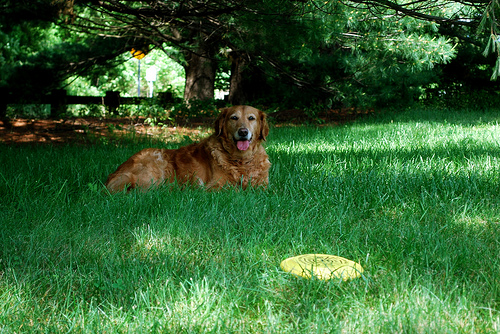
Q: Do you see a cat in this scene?
A: No, there are no cats.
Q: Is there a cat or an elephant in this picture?
A: No, there are no cats or elephants.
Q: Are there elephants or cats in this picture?
A: No, there are no cats or elephants.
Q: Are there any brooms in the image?
A: No, there are no brooms.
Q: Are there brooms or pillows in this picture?
A: No, there are no brooms or pillows.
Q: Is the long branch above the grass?
A: Yes, the branch is above the grass.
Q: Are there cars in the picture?
A: No, there are no cars.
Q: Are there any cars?
A: No, there are no cars.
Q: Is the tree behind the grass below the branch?
A: Yes, the tree is behind the grass.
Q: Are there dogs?
A: Yes, there is a dog.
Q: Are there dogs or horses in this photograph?
A: Yes, there is a dog.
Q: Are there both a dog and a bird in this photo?
A: No, there is a dog but no birds.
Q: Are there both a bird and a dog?
A: No, there is a dog but no birds.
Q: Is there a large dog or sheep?
A: Yes, there is a large dog.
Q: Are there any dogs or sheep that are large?
A: Yes, the dog is large.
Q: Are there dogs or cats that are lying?
A: Yes, the dog is lying.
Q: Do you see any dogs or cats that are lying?
A: Yes, the dog is lying.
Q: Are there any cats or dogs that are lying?
A: Yes, the dog is lying.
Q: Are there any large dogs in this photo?
A: Yes, there is a large dog.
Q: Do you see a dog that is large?
A: Yes, there is a dog that is large.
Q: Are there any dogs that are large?
A: Yes, there is a dog that is large.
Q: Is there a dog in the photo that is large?
A: Yes, there is a dog that is large.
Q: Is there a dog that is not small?
A: Yes, there is a large dog.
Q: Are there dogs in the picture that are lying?
A: Yes, there is a dog that is lying.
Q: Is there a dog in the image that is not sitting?
A: Yes, there is a dog that is lying.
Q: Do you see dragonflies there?
A: No, there are no dragonflies.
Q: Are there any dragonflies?
A: No, there are no dragonflies.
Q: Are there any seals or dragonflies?
A: No, there are no dragonflies or seals.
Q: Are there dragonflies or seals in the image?
A: No, there are no dragonflies or seals.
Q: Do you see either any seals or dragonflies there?
A: No, there are no dragonflies or seals.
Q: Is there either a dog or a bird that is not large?
A: No, there is a dog but it is large.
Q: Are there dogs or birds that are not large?
A: No, there is a dog but it is large.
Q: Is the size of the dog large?
A: Yes, the dog is large.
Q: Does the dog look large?
A: Yes, the dog is large.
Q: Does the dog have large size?
A: Yes, the dog is large.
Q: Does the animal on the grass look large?
A: Yes, the dog is large.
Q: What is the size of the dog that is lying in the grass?
A: The dog is large.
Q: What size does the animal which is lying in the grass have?
A: The dog has large size.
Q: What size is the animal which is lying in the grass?
A: The dog is large.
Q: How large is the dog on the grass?
A: The dog is large.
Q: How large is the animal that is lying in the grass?
A: The dog is large.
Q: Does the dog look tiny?
A: No, the dog is large.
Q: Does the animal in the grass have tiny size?
A: No, the dog is large.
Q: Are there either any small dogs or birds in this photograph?
A: No, there is a dog but it is large.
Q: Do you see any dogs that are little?
A: No, there is a dog but it is large.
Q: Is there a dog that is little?
A: No, there is a dog but it is large.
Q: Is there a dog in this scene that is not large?
A: No, there is a dog but it is large.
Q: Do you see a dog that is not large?
A: No, there is a dog but it is large.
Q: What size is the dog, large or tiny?
A: The dog is large.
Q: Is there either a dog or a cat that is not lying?
A: No, there is a dog but it is lying.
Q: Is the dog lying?
A: Yes, the dog is lying.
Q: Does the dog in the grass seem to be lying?
A: Yes, the dog is lying.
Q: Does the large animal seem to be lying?
A: Yes, the dog is lying.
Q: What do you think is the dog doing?
A: The dog is lying.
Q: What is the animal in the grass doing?
A: The dog is lying.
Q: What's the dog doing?
A: The dog is lying.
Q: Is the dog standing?
A: No, the dog is lying.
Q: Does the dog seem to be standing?
A: No, the dog is lying.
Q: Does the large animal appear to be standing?
A: No, the dog is lying.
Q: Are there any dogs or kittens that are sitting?
A: No, there is a dog but it is lying.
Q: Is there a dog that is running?
A: No, there is a dog but it is lying.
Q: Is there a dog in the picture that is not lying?
A: No, there is a dog but it is lying.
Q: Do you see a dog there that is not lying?
A: No, there is a dog but it is lying.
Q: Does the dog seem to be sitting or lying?
A: The dog is lying.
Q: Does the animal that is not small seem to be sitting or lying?
A: The dog is lying.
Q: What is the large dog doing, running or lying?
A: The dog is lying.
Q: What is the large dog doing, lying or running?
A: The dog is lying.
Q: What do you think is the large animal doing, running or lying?
A: The dog is lying.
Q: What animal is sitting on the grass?
A: The dog is sitting on the grass.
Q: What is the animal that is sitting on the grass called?
A: The animal is a dog.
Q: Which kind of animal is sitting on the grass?
A: The animal is a dog.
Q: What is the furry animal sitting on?
A: The dog is sitting on the grass.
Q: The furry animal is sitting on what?
A: The dog is sitting on the grass.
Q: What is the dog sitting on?
A: The dog is sitting on the grass.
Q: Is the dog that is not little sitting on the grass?
A: Yes, the dog is sitting on the grass.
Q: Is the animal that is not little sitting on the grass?
A: Yes, the dog is sitting on the grass.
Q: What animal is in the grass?
A: The animal is a dog.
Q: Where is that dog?
A: The dog is in the grass.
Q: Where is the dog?
A: The dog is in the grass.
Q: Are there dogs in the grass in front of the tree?
A: Yes, there is a dog in the grass.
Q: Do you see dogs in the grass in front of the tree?
A: Yes, there is a dog in the grass.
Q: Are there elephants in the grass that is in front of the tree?
A: No, there is a dog in the grass.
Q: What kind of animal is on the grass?
A: The animal is a dog.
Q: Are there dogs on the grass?
A: Yes, there is a dog on the grass.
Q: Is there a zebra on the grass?
A: No, there is a dog on the grass.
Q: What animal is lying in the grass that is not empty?
A: The animal is a dog.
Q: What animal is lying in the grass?
A: The animal is a dog.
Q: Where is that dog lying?
A: The dog is lying in the grass.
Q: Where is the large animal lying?
A: The dog is lying in the grass.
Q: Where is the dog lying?
A: The dog is lying in the grass.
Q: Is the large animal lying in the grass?
A: Yes, the dog is lying in the grass.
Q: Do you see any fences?
A: Yes, there is a fence.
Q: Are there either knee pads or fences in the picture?
A: Yes, there is a fence.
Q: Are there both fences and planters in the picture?
A: No, there is a fence but no planters.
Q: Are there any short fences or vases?
A: Yes, there is a short fence.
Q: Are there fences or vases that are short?
A: Yes, the fence is short.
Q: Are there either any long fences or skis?
A: Yes, there is a long fence.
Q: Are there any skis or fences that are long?
A: Yes, the fence is long.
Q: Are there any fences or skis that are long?
A: Yes, the fence is long.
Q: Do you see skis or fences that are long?
A: Yes, the fence is long.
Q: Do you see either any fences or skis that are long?
A: Yes, the fence is long.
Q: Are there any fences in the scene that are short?
A: Yes, there is a short fence.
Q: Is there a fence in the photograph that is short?
A: Yes, there is a fence that is short.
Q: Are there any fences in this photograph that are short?
A: Yes, there is a fence that is short.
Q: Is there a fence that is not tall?
A: Yes, there is a short fence.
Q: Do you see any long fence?
A: Yes, there is a long fence.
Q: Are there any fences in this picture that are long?
A: Yes, there is a fence that is long.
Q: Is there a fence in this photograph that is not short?
A: Yes, there is a long fence.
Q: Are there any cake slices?
A: No, there are no cake slices.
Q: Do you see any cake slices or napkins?
A: No, there are no cake slices or napkins.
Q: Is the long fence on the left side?
A: Yes, the fence is on the left of the image.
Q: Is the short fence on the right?
A: No, the fence is on the left of the image.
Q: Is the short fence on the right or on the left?
A: The fence is on the left of the image.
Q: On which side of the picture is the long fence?
A: The fence is on the left of the image.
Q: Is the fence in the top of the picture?
A: Yes, the fence is in the top of the image.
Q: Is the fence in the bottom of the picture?
A: No, the fence is in the top of the image.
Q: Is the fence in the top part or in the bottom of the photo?
A: The fence is in the top of the image.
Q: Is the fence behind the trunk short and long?
A: Yes, the fence is short and long.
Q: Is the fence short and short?
A: No, the fence is short but long.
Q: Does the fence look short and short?
A: No, the fence is short but long.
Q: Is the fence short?
A: Yes, the fence is short.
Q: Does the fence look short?
A: Yes, the fence is short.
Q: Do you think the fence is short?
A: Yes, the fence is short.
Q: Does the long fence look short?
A: Yes, the fence is short.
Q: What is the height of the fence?
A: The fence is short.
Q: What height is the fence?
A: The fence is short.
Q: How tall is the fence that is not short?
A: The fence is short.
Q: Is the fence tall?
A: No, the fence is short.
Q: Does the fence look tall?
A: No, the fence is short.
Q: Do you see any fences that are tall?
A: No, there is a fence but it is short.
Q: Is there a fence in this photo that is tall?
A: No, there is a fence but it is short.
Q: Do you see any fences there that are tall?
A: No, there is a fence but it is short.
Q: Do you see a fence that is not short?
A: No, there is a fence but it is short.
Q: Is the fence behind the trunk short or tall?
A: The fence is short.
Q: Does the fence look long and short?
A: Yes, the fence is long and short.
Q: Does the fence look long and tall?
A: No, the fence is long but short.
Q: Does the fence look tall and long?
A: No, the fence is long but short.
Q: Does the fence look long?
A: Yes, the fence is long.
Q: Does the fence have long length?
A: Yes, the fence is long.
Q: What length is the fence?
A: The fence is long.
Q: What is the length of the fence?
A: The fence is long.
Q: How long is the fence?
A: The fence is long.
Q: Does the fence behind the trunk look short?
A: No, the fence is long.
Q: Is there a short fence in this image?
A: No, there is a fence but it is long.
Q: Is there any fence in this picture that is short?
A: No, there is a fence but it is long.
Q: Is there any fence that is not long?
A: No, there is a fence but it is long.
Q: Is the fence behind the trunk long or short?
A: The fence is long.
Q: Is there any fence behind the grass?
A: Yes, there is a fence behind the grass.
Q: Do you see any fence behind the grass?
A: Yes, there is a fence behind the grass.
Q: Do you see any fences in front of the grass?
A: No, the fence is behind the grass.